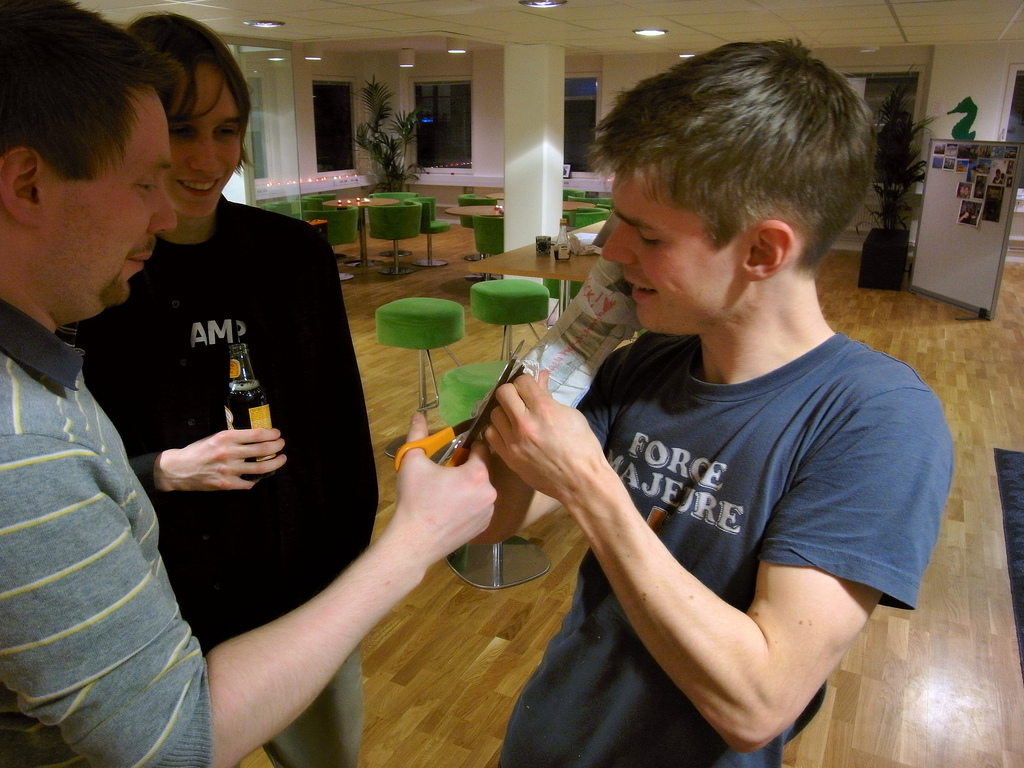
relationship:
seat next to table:
[383, 285, 470, 350] [383, 178, 535, 350]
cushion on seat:
[375, 297, 464, 354] [383, 285, 470, 350]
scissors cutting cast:
[322, 380, 563, 467] [504, 260, 639, 390]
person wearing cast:
[60, 152, 409, 664] [504, 260, 639, 390]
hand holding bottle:
[221, 329, 278, 451] [206, 342, 301, 442]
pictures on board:
[897, 121, 1021, 254] [897, 121, 1021, 254]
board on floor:
[897, 121, 1021, 254] [932, 312, 993, 760]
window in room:
[392, 75, 498, 158] [392, 75, 1018, 547]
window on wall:
[392, 75, 498, 158] [258, 48, 509, 187]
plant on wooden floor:
[334, 82, 430, 178] [396, 599, 502, 764]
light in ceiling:
[253, 0, 286, 33] [243, 9, 769, 93]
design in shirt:
[616, 420, 750, 559] [579, 342, 960, 704]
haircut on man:
[618, 75, 907, 275] [422, 75, 907, 766]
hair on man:
[603, 31, 878, 245] [422, 75, 907, 766]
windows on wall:
[308, 72, 360, 172] [382, 345, 504, 441]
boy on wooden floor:
[571, 86, 834, 660] [873, 606, 994, 764]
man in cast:
[5, 4, 224, 767] [530, 301, 636, 388]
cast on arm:
[530, 301, 636, 388] [563, 445, 836, 722]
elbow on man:
[702, 638, 849, 718] [568, 70, 850, 718]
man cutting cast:
[568, 70, 850, 718] [504, 260, 639, 390]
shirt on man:
[8, 322, 217, 702] [5, 3, 183, 764]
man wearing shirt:
[5, 3, 183, 764] [8, 322, 217, 702]